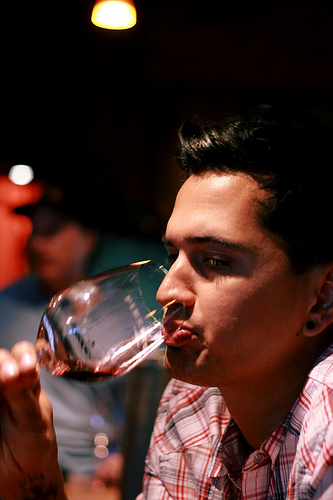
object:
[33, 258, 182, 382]
nearly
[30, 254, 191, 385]
glass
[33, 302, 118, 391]
wine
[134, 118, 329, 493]
man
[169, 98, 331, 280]
hair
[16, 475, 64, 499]
tattoo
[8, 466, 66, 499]
wrist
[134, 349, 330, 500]
shirt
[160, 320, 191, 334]
lips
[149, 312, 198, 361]
sip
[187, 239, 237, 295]
eye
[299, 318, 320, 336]
earring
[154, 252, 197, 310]
nose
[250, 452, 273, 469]
button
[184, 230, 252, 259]
eyebrow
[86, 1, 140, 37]
light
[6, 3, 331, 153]
ceiling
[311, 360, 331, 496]
stripes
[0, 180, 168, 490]
man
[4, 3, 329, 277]
back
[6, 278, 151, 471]
shirt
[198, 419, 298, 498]
collar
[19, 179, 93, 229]
cap